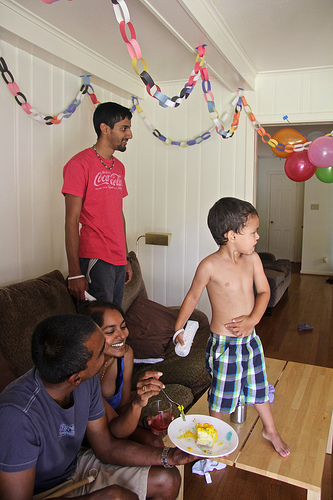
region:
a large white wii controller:
[168, 315, 197, 356]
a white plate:
[166, 413, 239, 458]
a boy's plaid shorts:
[205, 333, 269, 411]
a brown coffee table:
[155, 358, 331, 499]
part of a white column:
[139, 0, 254, 93]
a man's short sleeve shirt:
[0, 370, 106, 491]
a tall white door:
[266, 172, 304, 264]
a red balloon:
[285, 147, 316, 182]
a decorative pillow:
[123, 293, 180, 360]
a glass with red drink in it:
[146, 398, 172, 435]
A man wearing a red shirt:
[47, 92, 143, 302]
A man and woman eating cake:
[11, 294, 248, 489]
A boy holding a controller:
[168, 185, 291, 443]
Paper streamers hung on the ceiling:
[117, 26, 210, 111]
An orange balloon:
[265, 125, 308, 154]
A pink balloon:
[306, 133, 332, 168]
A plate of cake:
[166, 404, 242, 463]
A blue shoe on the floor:
[293, 318, 317, 338]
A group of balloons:
[265, 125, 331, 188]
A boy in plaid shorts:
[185, 200, 294, 462]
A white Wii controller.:
[174, 315, 199, 356]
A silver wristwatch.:
[156, 440, 175, 470]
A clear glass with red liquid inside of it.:
[148, 398, 175, 438]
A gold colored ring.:
[138, 385, 148, 393]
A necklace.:
[91, 142, 117, 172]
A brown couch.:
[2, 251, 213, 420]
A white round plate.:
[164, 409, 240, 464]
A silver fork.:
[154, 381, 192, 419]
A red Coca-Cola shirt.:
[62, 146, 129, 265]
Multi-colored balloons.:
[269, 129, 332, 182]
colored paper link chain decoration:
[144, 84, 265, 154]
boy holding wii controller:
[176, 188, 297, 443]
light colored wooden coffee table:
[277, 351, 328, 499]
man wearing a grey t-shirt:
[11, 294, 110, 494]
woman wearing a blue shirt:
[74, 297, 148, 401]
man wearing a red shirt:
[56, 120, 179, 298]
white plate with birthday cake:
[166, 407, 242, 481]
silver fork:
[160, 390, 190, 424]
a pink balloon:
[309, 131, 331, 170]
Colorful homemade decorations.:
[1, 0, 329, 160]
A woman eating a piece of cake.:
[84, 298, 245, 475]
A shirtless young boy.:
[186, 202, 293, 458]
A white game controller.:
[160, 317, 201, 357]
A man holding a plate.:
[1, 316, 241, 499]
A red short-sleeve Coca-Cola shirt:
[57, 146, 140, 271]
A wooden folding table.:
[175, 345, 330, 496]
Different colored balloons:
[270, 118, 330, 185]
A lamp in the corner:
[126, 227, 169, 292]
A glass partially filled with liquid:
[141, 392, 178, 441]